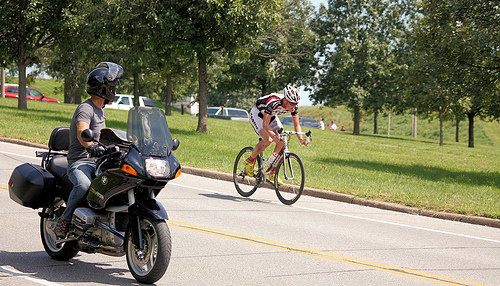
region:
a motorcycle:
[1, 50, 195, 276]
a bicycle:
[231, 84, 330, 225]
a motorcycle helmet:
[66, 57, 138, 104]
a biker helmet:
[281, 84, 308, 103]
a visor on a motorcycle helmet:
[89, 52, 133, 78]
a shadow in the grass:
[316, 153, 498, 195]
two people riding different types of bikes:
[13, 50, 335, 281]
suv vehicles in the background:
[4, 70, 317, 120]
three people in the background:
[317, 114, 356, 133]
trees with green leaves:
[24, 17, 242, 63]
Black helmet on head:
[81, 35, 145, 117]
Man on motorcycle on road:
[37, 32, 163, 284]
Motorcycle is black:
[23, 72, 182, 272]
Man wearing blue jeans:
[61, 157, 88, 197]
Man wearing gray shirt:
[47, 55, 141, 195]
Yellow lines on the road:
[200, 195, 257, 276]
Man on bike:
[223, 130, 330, 230]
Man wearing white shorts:
[236, 103, 275, 146]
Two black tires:
[238, 127, 328, 192]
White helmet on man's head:
[254, 70, 316, 137]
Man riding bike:
[235, 72, 322, 203]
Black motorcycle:
[33, 52, 208, 258]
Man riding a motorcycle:
[24, 46, 210, 276]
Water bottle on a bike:
[263, 154, 285, 168]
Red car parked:
[3, 77, 59, 105]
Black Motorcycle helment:
[77, 57, 134, 104]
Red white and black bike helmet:
[282, 80, 316, 107]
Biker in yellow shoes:
[245, 151, 261, 181]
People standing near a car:
[316, 107, 352, 144]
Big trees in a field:
[320, 7, 493, 160]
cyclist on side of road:
[222, 73, 327, 205]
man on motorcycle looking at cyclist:
[17, 57, 179, 274]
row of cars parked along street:
[3, 73, 328, 129]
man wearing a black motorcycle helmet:
[72, 61, 132, 112]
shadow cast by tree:
[303, 158, 497, 188]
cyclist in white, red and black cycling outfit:
[224, 84, 340, 205]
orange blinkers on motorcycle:
[113, 158, 193, 188]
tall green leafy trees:
[347, 10, 481, 136]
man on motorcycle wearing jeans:
[35, 42, 125, 255]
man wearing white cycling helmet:
[272, 81, 312, 116]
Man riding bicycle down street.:
[220, 76, 330, 214]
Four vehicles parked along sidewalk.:
[0, 78, 335, 138]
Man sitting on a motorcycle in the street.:
[1, 57, 191, 283]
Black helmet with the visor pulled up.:
[75, 55, 126, 111]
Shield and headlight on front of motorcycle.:
[112, 101, 199, 200]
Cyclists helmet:
[275, 83, 315, 108]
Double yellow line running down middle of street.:
[221, 222, 375, 281]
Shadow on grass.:
[320, 150, 495, 190]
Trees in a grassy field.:
[326, 10, 487, 159]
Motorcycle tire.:
[117, 200, 184, 283]